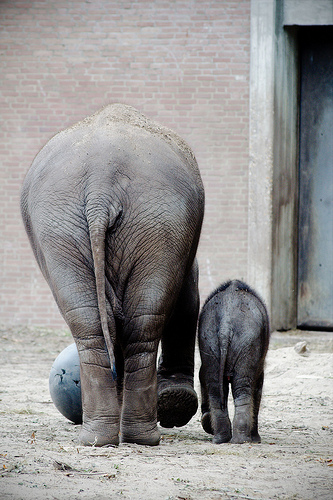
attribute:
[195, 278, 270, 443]
elephant — baby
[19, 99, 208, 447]
elephant — big, gray, round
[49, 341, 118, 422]
ball — large, blue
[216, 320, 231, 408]
tail — small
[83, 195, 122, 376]
tail — large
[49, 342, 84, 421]
ball — blue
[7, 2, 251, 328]
wall — red, bricked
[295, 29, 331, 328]
door — dark, rusty, metal